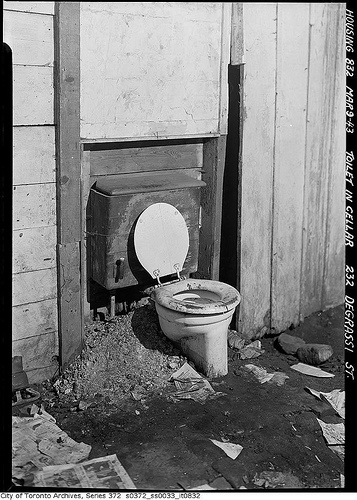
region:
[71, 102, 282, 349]
The picture is black and white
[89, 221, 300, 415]
This is a toilet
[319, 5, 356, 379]
This is the picture location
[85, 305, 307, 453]
Dirt surrounds the toilet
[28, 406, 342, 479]
Old papers are ripped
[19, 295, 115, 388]
Wood makes up the wall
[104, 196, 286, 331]
The lid is up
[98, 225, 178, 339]
This handle flushes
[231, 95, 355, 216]
The boards are vertical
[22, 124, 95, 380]
The boards are horizontal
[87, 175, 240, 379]
dirty porcelain toilet in the cellar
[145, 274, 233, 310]
dirty toilet seat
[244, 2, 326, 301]
black and white photo of a wood plank wall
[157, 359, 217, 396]
1940 newspaper used as toilet paper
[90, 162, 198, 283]
1943 toilet tank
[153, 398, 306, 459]
1940 dirt cellar floor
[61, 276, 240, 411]
black and white photo of debris next to toilet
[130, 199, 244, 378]
black and white photo of a 1940's toilet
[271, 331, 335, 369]
black and white rocks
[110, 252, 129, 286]
flushing handle of a 1940 toilet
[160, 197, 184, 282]
part of a toilet lead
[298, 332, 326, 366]
a stone on the ground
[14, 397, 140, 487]
torn old newspapers on the ground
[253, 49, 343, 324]
a wooden tall fence next to the toilet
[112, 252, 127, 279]
a small flash handle on the tank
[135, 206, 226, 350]
a dirty flash toilet exposed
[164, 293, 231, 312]
part of another lead of the flash toilet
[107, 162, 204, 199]
top of the toilet tank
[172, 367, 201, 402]
other torn newspapers on the ground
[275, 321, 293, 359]
another stone on the ground next to the fence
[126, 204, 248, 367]
an old toilet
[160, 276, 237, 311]
a worn toilet seat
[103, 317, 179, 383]
debris next to a toilet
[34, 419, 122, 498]
newspapers on the ground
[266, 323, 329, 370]
rocks next to a wood board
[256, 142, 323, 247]
wooden side of a building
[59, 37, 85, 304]
wood corner post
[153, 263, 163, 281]
the hinge on a toilet seat cover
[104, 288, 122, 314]
metal toilet pipe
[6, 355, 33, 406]
an old ice skate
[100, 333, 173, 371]
the gravel is grey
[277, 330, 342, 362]
the stones are grey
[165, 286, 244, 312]
dark spots are on the toilet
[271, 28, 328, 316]
the planks are made of wood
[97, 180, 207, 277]
the toilet top is grey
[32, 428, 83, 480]
the newspaper are wrinnkled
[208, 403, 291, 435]
the ground is dark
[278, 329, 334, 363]
two stones next to each other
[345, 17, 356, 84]
white writing on the side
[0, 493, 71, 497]
black writing at the bottom